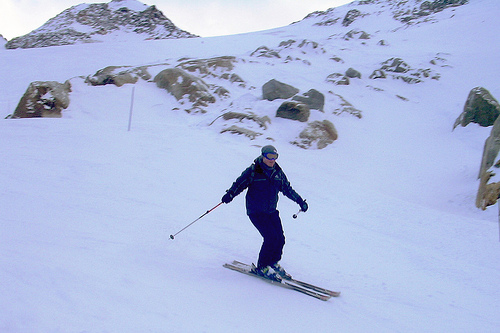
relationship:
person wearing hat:
[221, 144, 308, 282] [261, 144, 277, 155]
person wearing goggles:
[221, 144, 308, 282] [262, 150, 279, 159]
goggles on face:
[262, 150, 279, 159] [263, 151, 279, 166]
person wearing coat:
[221, 144, 308, 282] [228, 156, 302, 214]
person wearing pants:
[221, 144, 308, 282] [247, 208, 285, 268]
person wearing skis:
[221, 144, 308, 282] [223, 260, 341, 300]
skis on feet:
[223, 260, 341, 300] [251, 262, 291, 282]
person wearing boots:
[221, 144, 308, 282] [251, 262, 291, 282]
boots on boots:
[254, 258, 291, 280] [251, 262, 291, 282]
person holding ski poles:
[221, 144, 308, 282] [168, 198, 307, 242]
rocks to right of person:
[450, 85, 500, 208] [221, 144, 308, 282]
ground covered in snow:
[0, 0, 498, 332] [0, 0, 499, 333]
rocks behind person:
[0, 1, 499, 209] [221, 144, 308, 282]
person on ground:
[221, 144, 308, 282] [0, 0, 498, 332]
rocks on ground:
[0, 1, 499, 209] [0, 0, 498, 332]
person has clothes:
[221, 144, 308, 282] [222, 159, 302, 267]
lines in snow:
[0, 131, 498, 332] [0, 0, 499, 333]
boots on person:
[254, 258, 291, 280] [221, 144, 308, 282]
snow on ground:
[0, 0, 499, 333] [0, 0, 498, 332]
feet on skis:
[251, 262, 291, 282] [223, 260, 341, 300]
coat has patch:
[228, 156, 302, 214] [251, 162, 264, 178]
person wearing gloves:
[221, 144, 308, 282] [221, 190, 309, 212]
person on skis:
[221, 144, 308, 282] [223, 260, 341, 300]